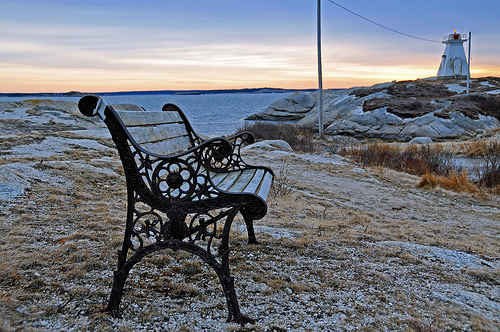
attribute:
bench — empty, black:
[76, 94, 274, 325]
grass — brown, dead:
[276, 188, 492, 281]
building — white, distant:
[440, 34, 471, 79]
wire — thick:
[328, 0, 475, 53]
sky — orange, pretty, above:
[1, 4, 500, 91]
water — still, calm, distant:
[115, 88, 269, 107]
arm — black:
[138, 130, 258, 197]